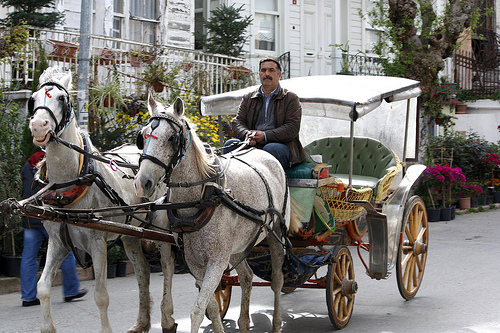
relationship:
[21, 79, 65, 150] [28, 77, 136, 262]
face of horse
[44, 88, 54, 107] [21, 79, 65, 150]
spot on face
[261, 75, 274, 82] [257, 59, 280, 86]
mustache on face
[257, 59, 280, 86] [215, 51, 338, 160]
face of man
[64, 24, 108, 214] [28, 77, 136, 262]
pole in front of horse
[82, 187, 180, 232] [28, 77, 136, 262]
rod in front of horse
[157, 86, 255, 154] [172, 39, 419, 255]
flowers behind carriage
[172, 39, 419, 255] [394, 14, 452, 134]
carriage behind tree